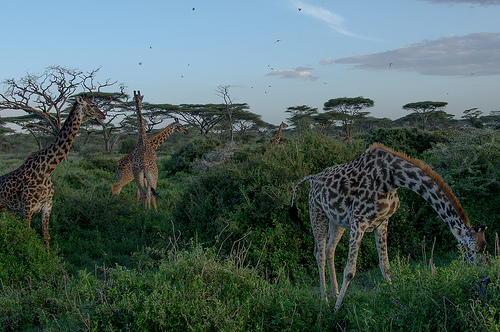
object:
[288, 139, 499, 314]
giraffe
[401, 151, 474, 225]
neck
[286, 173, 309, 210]
tail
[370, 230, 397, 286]
leg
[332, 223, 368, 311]
leg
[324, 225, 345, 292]
leg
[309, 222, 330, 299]
leg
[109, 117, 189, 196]
giraffe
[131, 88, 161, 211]
giraffe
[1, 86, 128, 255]
giraffe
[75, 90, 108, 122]
visible head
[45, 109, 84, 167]
visible neck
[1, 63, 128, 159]
tree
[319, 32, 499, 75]
cloud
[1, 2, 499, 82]
sky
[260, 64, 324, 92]
cloud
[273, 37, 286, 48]
bird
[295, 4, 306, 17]
bird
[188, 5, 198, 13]
bird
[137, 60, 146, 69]
bird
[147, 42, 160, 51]
bird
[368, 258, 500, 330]
grass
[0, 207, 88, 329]
bush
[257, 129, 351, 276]
bush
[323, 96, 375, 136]
tree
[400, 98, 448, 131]
tree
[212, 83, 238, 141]
tree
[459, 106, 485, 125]
small green tree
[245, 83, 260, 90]
birds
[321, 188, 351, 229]
tummy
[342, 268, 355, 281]
knee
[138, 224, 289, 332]
plant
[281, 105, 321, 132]
shade tree